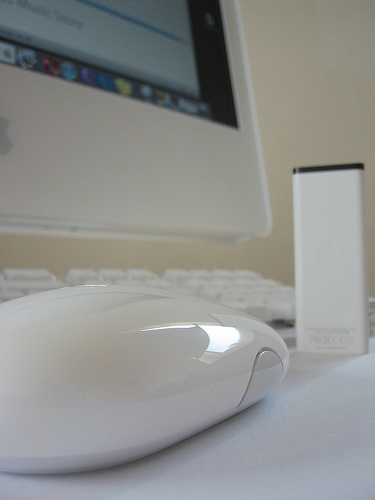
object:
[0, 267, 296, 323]
keyboard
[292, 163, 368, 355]
box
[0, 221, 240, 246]
grille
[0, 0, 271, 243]
computer monitor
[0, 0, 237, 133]
computer screen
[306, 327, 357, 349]
macintosh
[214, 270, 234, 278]
key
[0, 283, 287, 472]
mouse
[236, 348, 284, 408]
button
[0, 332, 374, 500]
desk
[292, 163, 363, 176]
top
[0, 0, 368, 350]
imac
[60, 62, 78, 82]
app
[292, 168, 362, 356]
back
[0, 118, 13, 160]
logo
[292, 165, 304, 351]
pole